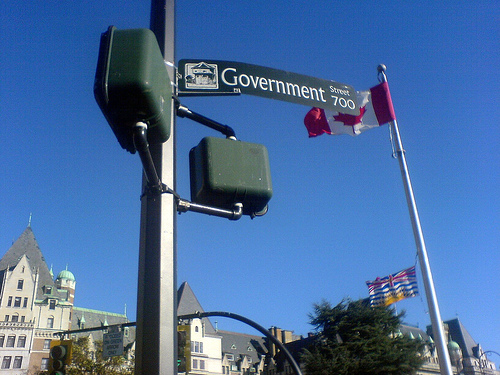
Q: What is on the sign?
A: A word.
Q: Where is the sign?
A: Above the pole.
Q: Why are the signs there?
A: For directions.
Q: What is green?
A: The trees.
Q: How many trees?
A: 2.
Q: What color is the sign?
A: Green and white.